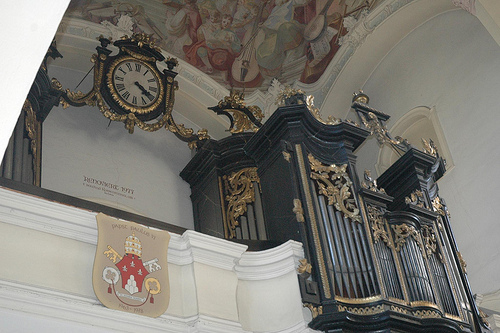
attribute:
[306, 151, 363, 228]
design — gold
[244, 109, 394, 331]
column — black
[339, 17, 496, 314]
wall — building wall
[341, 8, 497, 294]
wall — clear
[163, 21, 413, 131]
ceiling — building ceiling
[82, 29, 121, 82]
trim — golden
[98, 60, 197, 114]
clock — black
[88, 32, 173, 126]
clock — metal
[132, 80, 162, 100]
hands — black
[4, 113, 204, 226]
wall — building wall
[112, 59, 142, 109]
numerals — black, roman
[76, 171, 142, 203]
writing — gold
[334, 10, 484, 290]
paint — white